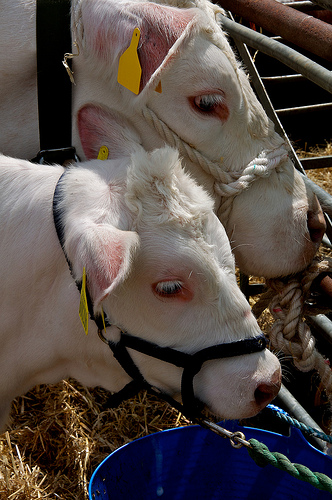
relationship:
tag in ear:
[105, 11, 160, 99] [41, 194, 169, 352]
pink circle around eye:
[148, 273, 189, 301] [155, 280, 180, 297]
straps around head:
[47, 182, 251, 388] [0, 153, 283, 422]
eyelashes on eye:
[182, 93, 235, 106] [152, 279, 186, 295]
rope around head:
[139, 103, 292, 241] [72, 2, 330, 286]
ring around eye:
[151, 275, 193, 302] [175, 73, 239, 126]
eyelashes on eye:
[140, 263, 191, 303] [154, 278, 185, 296]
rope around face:
[139, 103, 292, 241] [128, 3, 326, 279]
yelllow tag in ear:
[111, 21, 148, 97] [121, 4, 169, 77]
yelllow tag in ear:
[75, 268, 97, 332] [72, 224, 142, 317]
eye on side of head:
[188, 89, 240, 123] [84, 147, 295, 435]